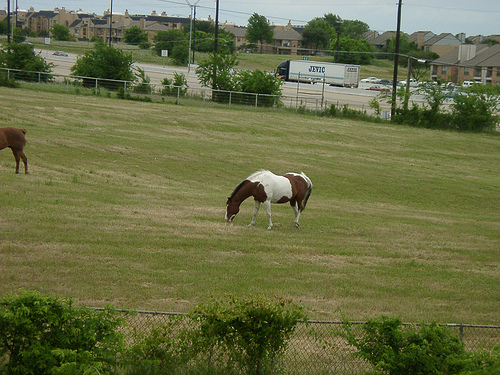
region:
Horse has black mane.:
[222, 178, 253, 199]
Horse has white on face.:
[219, 200, 231, 224]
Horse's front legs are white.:
[250, 199, 280, 229]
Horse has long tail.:
[301, 179, 320, 213]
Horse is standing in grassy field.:
[211, 180, 256, 245]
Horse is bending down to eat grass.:
[218, 171, 248, 234]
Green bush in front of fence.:
[351, 312, 449, 372]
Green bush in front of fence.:
[197, 306, 309, 364]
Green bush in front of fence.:
[37, 298, 102, 353]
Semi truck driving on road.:
[271, 52, 389, 104]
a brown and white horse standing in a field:
[198, 143, 330, 252]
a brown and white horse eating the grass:
[208, 163, 324, 240]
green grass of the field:
[94, 198, 163, 255]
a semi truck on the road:
[271, 50, 364, 93]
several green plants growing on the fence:
[13, 290, 450, 370]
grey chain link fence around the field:
[293, 320, 342, 367]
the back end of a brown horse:
[0, 107, 42, 187]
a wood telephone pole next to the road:
[384, 3, 411, 118]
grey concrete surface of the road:
[144, 61, 172, 85]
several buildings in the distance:
[24, 0, 474, 72]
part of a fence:
[325, 350, 333, 363]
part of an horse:
[281, 190, 289, 197]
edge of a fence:
[317, 324, 322, 334]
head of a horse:
[221, 196, 233, 231]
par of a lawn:
[171, 253, 186, 272]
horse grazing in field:
[214, 165, 318, 230]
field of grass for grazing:
[351, 133, 490, 296]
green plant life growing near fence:
[345, 306, 495, 372]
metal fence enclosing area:
[299, 320, 349, 370]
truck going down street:
[270, 54, 367, 91]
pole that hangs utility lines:
[388, 0, 405, 120]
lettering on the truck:
[307, 62, 331, 75]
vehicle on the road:
[52, 47, 67, 59]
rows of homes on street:
[5, 5, 297, 54]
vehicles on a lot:
[363, 70, 475, 92]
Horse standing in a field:
[186, 153, 326, 235]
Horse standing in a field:
[5, 123, 40, 158]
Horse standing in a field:
[209, 168, 276, 225]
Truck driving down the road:
[261, 40, 381, 97]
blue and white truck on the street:
[271, 52, 361, 97]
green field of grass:
[323, 151, 431, 303]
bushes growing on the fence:
[198, 294, 295, 349]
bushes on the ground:
[70, 31, 133, 89]